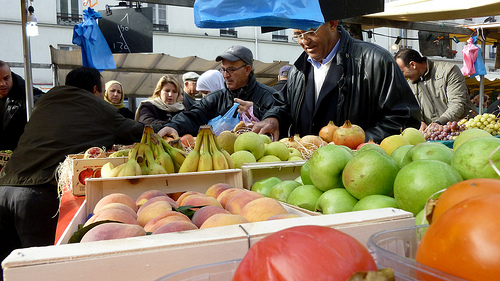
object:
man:
[394, 48, 479, 132]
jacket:
[405, 57, 479, 125]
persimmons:
[230, 225, 395, 281]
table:
[55, 142, 491, 278]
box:
[365, 223, 497, 281]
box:
[153, 258, 425, 280]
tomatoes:
[415, 177, 499, 281]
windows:
[57, 0, 81, 23]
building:
[1, 2, 498, 110]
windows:
[148, 3, 168, 32]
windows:
[220, 27, 236, 37]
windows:
[272, 28, 288, 42]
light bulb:
[26, 6, 39, 37]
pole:
[19, 0, 35, 121]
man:
[250, 20, 422, 144]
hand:
[252, 117, 279, 142]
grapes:
[424, 121, 465, 141]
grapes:
[458, 113, 500, 136]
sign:
[97, 7, 153, 55]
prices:
[113, 13, 131, 53]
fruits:
[76, 113, 500, 281]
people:
[0, 19, 479, 247]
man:
[155, 44, 278, 140]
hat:
[215, 45, 253, 68]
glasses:
[292, 25, 322, 45]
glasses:
[218, 65, 247, 74]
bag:
[72, 7, 118, 73]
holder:
[26, 6, 36, 22]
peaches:
[75, 182, 302, 243]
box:
[0, 206, 413, 281]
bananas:
[106, 124, 235, 179]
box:
[54, 169, 312, 245]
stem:
[140, 124, 155, 143]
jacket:
[261, 25, 421, 146]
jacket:
[164, 70, 284, 137]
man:
[0, 67, 163, 252]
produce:
[207, 103, 240, 137]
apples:
[251, 128, 499, 243]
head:
[222, 45, 254, 89]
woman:
[134, 74, 187, 133]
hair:
[149, 73, 184, 103]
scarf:
[135, 98, 185, 122]